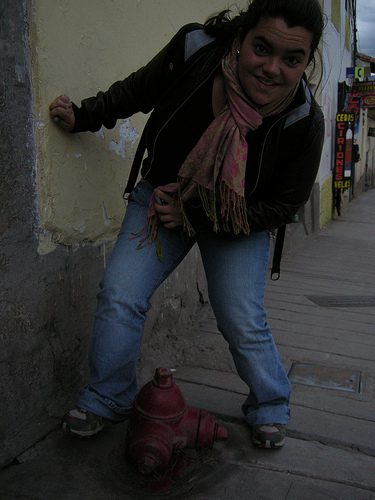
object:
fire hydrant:
[125, 362, 229, 499]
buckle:
[271, 219, 286, 281]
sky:
[354, 0, 373, 60]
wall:
[1, 3, 250, 465]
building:
[0, 2, 375, 466]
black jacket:
[71, 21, 325, 241]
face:
[236, 18, 304, 111]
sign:
[335, 124, 348, 190]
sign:
[340, 62, 367, 81]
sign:
[345, 89, 362, 127]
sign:
[362, 98, 374, 109]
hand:
[152, 186, 181, 231]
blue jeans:
[78, 182, 293, 425]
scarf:
[127, 53, 301, 259]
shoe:
[251, 423, 287, 451]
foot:
[244, 391, 288, 451]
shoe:
[55, 396, 129, 437]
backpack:
[121, 44, 320, 282]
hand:
[49, 94, 74, 131]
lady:
[50, 2, 323, 450]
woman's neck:
[213, 59, 303, 106]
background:
[308, 34, 374, 222]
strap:
[271, 223, 284, 282]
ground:
[0, 193, 368, 492]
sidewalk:
[0, 241, 375, 500]